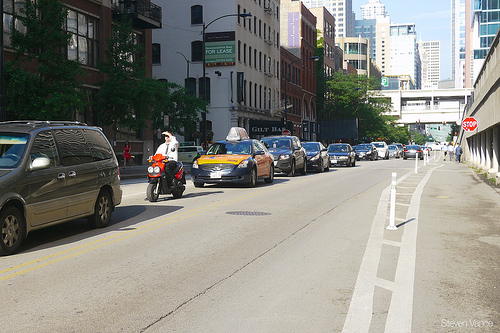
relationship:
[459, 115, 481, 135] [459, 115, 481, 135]
sign says sign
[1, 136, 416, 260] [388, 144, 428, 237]
street has dividers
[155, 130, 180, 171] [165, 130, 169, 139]
man shields eyes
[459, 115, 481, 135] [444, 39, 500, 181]
sign on building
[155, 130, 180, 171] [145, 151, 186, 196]
man on a scooter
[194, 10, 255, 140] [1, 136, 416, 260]
streetlight over street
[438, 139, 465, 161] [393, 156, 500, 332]
people walk on sidewalk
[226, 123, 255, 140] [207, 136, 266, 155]
sign on cartop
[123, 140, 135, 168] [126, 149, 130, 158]
woman wears red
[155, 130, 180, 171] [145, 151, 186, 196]
man on a red scooter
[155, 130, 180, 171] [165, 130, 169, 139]
man covering h eyes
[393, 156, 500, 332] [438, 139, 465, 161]
sidewalk has walking people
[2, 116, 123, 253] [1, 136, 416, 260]
minivan on street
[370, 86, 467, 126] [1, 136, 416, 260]
walkway over street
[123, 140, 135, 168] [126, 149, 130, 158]
woman in red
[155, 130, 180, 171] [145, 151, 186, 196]
man rides a scooter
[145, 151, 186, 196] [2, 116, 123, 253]
scooter behind a minivan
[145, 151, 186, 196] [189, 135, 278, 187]
scooter in from of a car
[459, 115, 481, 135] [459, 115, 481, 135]
sign on a sign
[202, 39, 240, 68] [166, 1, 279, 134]
sign on a building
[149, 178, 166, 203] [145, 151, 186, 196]
tire on scooter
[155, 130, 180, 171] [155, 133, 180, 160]
man wears a white shirt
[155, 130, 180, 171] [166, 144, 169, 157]
man wears a tie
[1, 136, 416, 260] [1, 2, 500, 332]
street in a city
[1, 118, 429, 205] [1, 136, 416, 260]
vehicles on street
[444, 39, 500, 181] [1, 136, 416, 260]
building on street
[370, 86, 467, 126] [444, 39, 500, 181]
walkway connects building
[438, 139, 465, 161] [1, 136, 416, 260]
people walking on street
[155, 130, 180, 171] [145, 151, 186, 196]
man on red scooter